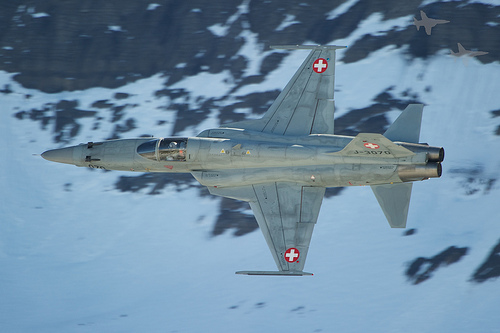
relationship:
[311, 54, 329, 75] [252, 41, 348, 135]
cross on right wing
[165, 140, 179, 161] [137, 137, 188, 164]
person in cockpit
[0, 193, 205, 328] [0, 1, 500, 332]
snow on ground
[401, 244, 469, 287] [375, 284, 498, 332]
ground showing through snow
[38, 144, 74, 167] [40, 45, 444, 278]
nose of plane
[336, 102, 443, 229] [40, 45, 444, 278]
tail of plane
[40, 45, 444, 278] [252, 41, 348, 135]
plane has right wing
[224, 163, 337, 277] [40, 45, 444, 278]
left wing of plane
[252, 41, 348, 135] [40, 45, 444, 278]
right wing of plane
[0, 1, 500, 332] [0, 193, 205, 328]
ground covered in snow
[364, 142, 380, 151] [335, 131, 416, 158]
cross on vertical stabilizer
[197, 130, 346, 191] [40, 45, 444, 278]
body of plane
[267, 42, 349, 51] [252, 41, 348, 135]
edge of right wing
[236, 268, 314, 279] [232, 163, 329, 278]
edge of left wing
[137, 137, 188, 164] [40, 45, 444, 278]
cockpit of plane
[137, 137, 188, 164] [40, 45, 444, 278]
cockpit on plane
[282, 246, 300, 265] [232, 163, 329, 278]
cross on left wing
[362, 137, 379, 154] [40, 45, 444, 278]
logo on plane